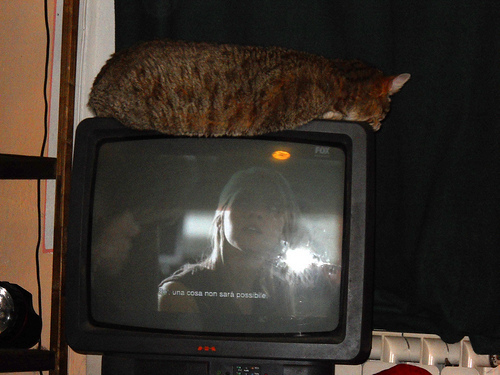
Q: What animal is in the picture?
A: A feline.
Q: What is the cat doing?
A: Laying down.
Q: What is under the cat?
A: A tv.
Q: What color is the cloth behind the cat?
A: Black.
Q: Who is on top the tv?
A: A cat.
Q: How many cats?
A: One.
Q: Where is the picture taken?
A: On top of a television.